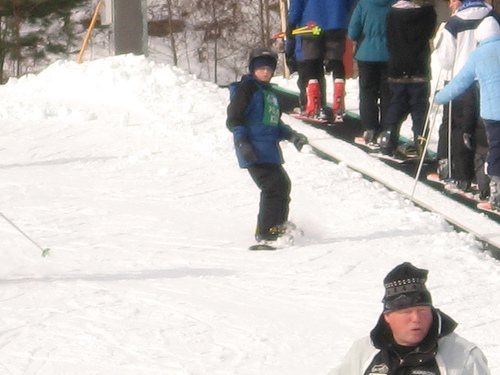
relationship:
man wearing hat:
[327, 259, 498, 375] [374, 257, 438, 310]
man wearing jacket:
[327, 259, 487, 373] [321, 333, 489, 374]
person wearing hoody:
[377, 0, 437, 160] [380, 0, 435, 84]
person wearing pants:
[377, 0, 437, 160] [380, 76, 430, 148]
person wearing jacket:
[347, 0, 400, 143] [345, 3, 392, 62]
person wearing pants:
[347, 0, 400, 143] [353, 62, 388, 151]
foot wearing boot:
[299, 105, 324, 114] [301, 80, 321, 115]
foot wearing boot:
[330, 107, 344, 114] [331, 82, 345, 112]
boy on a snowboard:
[219, 42, 317, 250] [216, 201, 344, 281]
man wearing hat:
[327, 259, 487, 373] [383, 261, 441, 304]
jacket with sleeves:
[228, 77, 310, 166] [225, 72, 285, 137]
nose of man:
[410, 311, 422, 323] [327, 259, 487, 373]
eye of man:
[403, 310, 411, 314] [327, 259, 487, 373]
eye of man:
[418, 310, 424, 315] [327, 259, 487, 373]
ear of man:
[379, 310, 394, 327] [327, 259, 487, 373]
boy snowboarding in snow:
[467, 27, 498, 92] [2, 46, 498, 373]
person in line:
[429, 15, 499, 211] [308, 112, 400, 202]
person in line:
[424, 0, 499, 188] [308, 112, 400, 202]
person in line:
[377, 0, 437, 160] [308, 112, 400, 202]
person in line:
[347, 0, 400, 143] [308, 112, 400, 202]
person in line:
[281, 0, 355, 121] [308, 112, 400, 202]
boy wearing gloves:
[219, 42, 321, 256] [233, 126, 318, 160]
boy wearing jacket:
[219, 42, 317, 250] [225, 71, 295, 168]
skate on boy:
[255, 229, 293, 246] [219, 42, 317, 250]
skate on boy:
[248, 222, 304, 251] [219, 42, 317, 250]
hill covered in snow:
[1, 50, 498, 372] [49, 78, 198, 135]